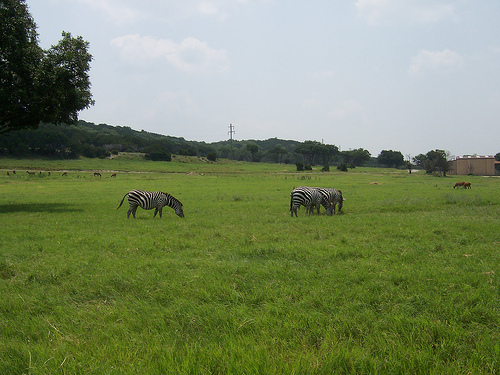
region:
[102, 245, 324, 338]
green grass in the field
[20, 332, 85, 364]
slivers of brown grass in the field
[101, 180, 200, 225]
zebra in the field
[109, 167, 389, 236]
zebra grazing in the field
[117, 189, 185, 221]
zebra grazing in green grass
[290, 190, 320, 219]
zebra grazing in green grass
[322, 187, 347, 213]
zebra grazing in green grass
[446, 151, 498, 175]
long tan and white building near trees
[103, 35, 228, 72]
large white cloud in the sky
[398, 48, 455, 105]
large white cloud in sky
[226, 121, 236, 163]
tall,brown utility pole near trees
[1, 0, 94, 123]
tall green trees near smaller trees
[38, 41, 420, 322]
these are a bunch of zebras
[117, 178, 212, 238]
the zebra is grazing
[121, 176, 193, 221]
the zebra is bent over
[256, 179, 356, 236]
these zebras are grazing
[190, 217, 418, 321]
the field is grassy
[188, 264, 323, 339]
the grass is medium height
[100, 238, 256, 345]
the grass is brown and green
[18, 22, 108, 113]
this tree is very tall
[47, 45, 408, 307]
this is an open field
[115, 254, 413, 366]
the grass is tall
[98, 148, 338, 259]
the zebras are grazing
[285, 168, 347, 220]
this is a group of zebras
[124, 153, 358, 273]
the zebras are striped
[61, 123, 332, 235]
the zebras are white and black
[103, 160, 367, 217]
a group of zebras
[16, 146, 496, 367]
a large open field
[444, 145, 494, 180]
building on the side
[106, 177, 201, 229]
the zebra is eating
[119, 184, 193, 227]
near zebra on left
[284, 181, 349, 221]
near group of zebras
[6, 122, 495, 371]
entire grass field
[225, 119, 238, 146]
telephone pole in center far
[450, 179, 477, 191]
far off brown animals on right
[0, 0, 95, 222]
nearest tree to camera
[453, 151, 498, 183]
tan shed on right far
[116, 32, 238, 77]
cloud in sky near center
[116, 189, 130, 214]
left zebra's tail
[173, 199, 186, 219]
left zebra's head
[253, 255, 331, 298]
grass the animals are standing on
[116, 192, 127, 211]
the zebra's tail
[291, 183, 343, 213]
two zebras in the middle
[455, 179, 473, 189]
brown horse in the distance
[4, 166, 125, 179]
group of animals in the distance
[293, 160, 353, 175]
bushes in the middle behind the animals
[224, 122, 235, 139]
wooden post supporting the cable lines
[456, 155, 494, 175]
tan building on the premises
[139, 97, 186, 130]
grey sky above the trees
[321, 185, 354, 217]
a zebra in the field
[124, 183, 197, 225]
a zebra in the field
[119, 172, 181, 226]
a zebra is grazing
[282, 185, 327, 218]
a zebra is grazing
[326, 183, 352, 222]
a zebra is grazing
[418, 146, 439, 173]
green leaves on the tree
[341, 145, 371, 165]
green leaves on the tree